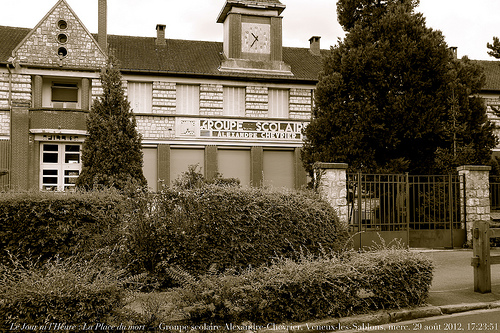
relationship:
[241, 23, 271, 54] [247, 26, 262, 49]
clock has hands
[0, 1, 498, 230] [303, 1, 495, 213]
building has tree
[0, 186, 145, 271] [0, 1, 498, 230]
bush in front of building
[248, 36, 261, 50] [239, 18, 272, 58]
hand on clock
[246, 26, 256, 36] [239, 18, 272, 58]
hand on clock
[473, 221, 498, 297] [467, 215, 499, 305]
post on fence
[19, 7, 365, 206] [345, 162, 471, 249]
school behind gate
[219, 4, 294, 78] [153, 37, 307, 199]
clock on cuppola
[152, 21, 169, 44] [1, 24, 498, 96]
chimney on roof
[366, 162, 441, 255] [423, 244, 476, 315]
gate behind sidewalk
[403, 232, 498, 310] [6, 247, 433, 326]
sidewalk behind hedge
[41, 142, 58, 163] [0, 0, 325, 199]
window in building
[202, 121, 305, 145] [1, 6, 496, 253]
letters on building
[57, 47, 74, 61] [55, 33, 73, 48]
circle on circle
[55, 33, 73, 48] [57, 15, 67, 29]
circle on circle